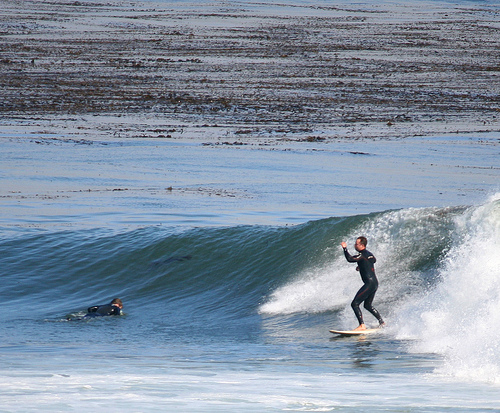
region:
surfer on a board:
[326, 232, 400, 340]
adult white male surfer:
[330, 229, 403, 343]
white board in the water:
[324, 325, 391, 339]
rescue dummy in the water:
[70, 291, 130, 327]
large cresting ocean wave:
[0, 181, 498, 403]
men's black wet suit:
[335, 243, 391, 332]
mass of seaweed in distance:
[2, 3, 497, 158]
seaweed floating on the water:
[3, 1, 497, 163]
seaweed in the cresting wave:
[147, 249, 197, 271]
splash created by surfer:
[379, 228, 499, 388]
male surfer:
[313, 215, 387, 344]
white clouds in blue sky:
[31, 21, 85, 91]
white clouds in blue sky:
[120, 11, 179, 74]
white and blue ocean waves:
[166, 320, 230, 366]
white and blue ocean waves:
[41, 145, 132, 205]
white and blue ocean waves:
[145, 155, 207, 210]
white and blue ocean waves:
[230, 280, 286, 321]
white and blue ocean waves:
[401, 198, 486, 295]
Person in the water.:
[323, 200, 455, 399]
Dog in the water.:
[40, 283, 150, 343]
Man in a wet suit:
[305, 220, 429, 356]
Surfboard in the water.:
[322, 298, 423, 348]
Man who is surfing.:
[316, 224, 475, 381]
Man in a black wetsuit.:
[286, 227, 409, 352]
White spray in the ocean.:
[241, 222, 427, 360]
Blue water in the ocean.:
[143, 90, 395, 277]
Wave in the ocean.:
[283, 192, 455, 358]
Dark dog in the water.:
[67, 273, 204, 355]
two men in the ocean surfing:
[35, 190, 465, 382]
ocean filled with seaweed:
[5, 8, 486, 143]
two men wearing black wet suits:
[41, 220, 408, 349]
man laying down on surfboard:
[25, 267, 165, 340]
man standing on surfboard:
[315, 225, 405, 340]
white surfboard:
[325, 320, 405, 343]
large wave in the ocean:
[38, 183, 486, 342]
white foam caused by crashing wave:
[425, 198, 495, 363]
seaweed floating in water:
[150, 245, 194, 276]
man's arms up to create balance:
[310, 223, 398, 339]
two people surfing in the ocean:
[72, 231, 423, 344]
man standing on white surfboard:
[305, 223, 409, 347]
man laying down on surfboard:
[44, 287, 131, 329]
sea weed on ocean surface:
[35, 172, 264, 209]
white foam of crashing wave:
[421, 236, 498, 373]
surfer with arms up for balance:
[306, 229, 400, 339]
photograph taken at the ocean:
[30, 156, 485, 391]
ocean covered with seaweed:
[46, 18, 466, 135]